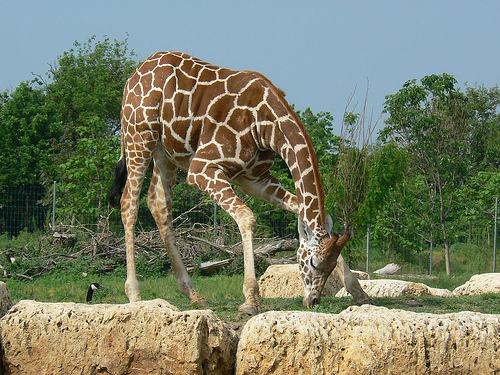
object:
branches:
[21, 214, 107, 276]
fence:
[0, 182, 500, 276]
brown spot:
[294, 143, 311, 172]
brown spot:
[172, 93, 192, 116]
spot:
[168, 65, 201, 93]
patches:
[167, 90, 190, 119]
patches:
[169, 117, 190, 138]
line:
[185, 87, 197, 140]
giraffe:
[120, 52, 348, 316]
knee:
[236, 209, 256, 229]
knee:
[157, 221, 176, 240]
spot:
[215, 123, 242, 160]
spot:
[234, 79, 266, 108]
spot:
[151, 67, 172, 88]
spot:
[125, 90, 144, 110]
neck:
[279, 101, 327, 228]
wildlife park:
[5, 34, 498, 372]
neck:
[87, 289, 95, 293]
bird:
[86, 282, 105, 301]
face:
[95, 283, 100, 289]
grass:
[0, 269, 500, 311]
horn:
[327, 234, 339, 249]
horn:
[336, 234, 350, 248]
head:
[297, 230, 352, 308]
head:
[94, 283, 104, 290]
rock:
[257, 264, 428, 299]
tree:
[374, 71, 499, 275]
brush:
[24, 210, 291, 284]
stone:
[1, 298, 234, 375]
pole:
[365, 225, 370, 270]